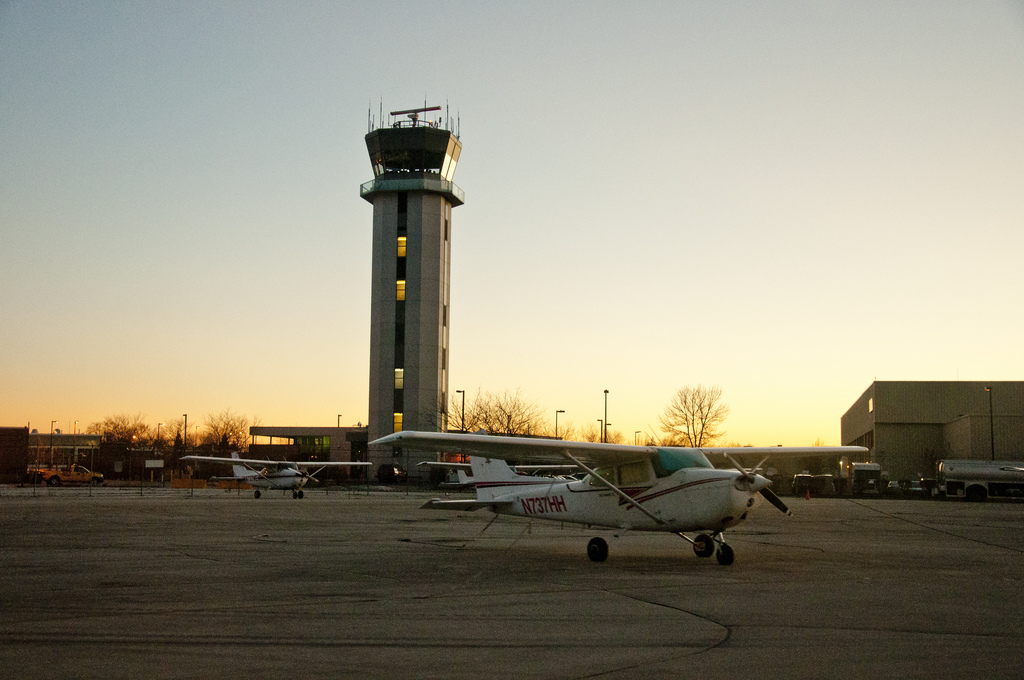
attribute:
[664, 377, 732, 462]
tree — behind a plane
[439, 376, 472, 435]
lamp post — black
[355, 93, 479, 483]
control tower — air traffic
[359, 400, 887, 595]
airplane — small, white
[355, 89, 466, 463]
traffic tower — air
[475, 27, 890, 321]
clouds — white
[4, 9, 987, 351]
sky — blue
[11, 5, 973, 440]
sky — blue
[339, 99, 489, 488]
tower — airplane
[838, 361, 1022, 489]
building — light colored, brick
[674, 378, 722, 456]
tree — with no leaves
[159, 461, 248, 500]
fence — orange, safety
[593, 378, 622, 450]
light — one, street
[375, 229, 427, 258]
glass — clear, clean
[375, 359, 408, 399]
glass — clean, clear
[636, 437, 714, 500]
glass — clear, clean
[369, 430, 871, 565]
airplane — small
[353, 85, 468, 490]
tower — communication, control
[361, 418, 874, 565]
airplane — small, private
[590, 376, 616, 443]
street light — tall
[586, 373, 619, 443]
street light — tall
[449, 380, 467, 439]
street light — tall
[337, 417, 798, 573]
plane — on runway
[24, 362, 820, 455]
sun — setting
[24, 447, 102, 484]
truck — yellow